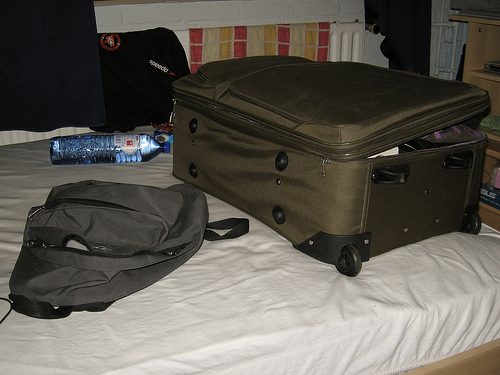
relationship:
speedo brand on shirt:
[145, 57, 174, 77] [90, 27, 190, 131]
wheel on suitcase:
[460, 209, 481, 236] [170, 52, 490, 276]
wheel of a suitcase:
[336, 244, 363, 278] [170, 52, 490, 276]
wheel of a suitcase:
[323, 235, 391, 289] [170, 52, 490, 276]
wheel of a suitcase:
[460, 209, 481, 236] [177, 40, 479, 285]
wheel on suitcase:
[336, 244, 363, 278] [170, 52, 490, 276]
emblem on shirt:
[97, 32, 123, 54] [74, 27, 194, 134]